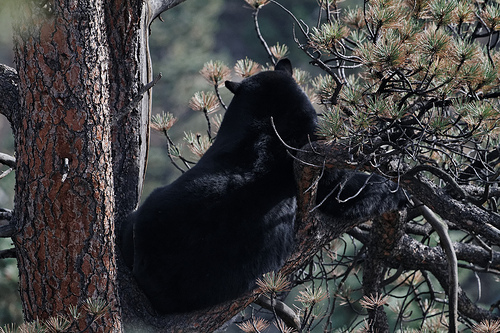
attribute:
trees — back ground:
[151, 7, 226, 75]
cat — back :
[143, 34, 363, 311]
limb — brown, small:
[415, 202, 460, 330]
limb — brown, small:
[250, 279, 317, 331]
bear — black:
[93, 43, 463, 332]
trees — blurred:
[159, 2, 312, 61]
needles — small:
[358, 47, 468, 153]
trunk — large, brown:
[8, 0, 128, 331]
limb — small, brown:
[411, 195, 466, 332]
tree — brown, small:
[311, 110, 482, 307]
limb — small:
[143, 66, 163, 93]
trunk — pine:
[12, 0, 114, 330]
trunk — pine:
[104, 1, 151, 238]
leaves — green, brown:
[293, 2, 499, 172]